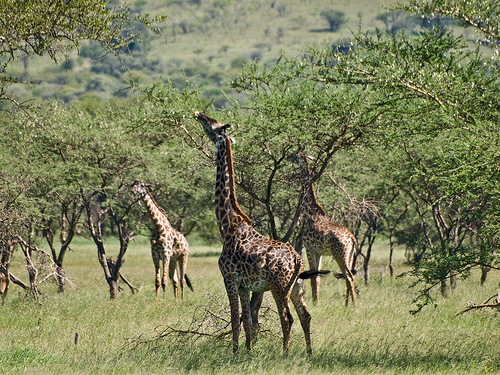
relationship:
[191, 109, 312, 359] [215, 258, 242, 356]
giraffe has leg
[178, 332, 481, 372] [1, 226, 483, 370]
shadow on ground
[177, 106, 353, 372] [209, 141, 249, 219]
giraffe has neck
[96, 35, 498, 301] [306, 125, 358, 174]
tree has limbs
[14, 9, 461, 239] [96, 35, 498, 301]
grove of tree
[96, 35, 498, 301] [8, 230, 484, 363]
tree in field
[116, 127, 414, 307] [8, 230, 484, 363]
giraffes grazing field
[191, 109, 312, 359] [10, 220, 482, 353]
giraffe in pasture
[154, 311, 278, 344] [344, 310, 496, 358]
branch on ground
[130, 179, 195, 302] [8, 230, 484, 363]
giraffe on field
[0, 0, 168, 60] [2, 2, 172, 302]
leaves on tree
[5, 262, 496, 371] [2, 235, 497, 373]
grass in field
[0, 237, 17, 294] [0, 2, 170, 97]
trunk of tree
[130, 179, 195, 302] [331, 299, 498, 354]
giraffe standing grass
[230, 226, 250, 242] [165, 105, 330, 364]
spot on giraffe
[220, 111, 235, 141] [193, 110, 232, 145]
ossicones on giraffe head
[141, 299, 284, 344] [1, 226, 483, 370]
fallen branches on ground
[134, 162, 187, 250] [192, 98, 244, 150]
giraffe has head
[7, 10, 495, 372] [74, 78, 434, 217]
photo has detail